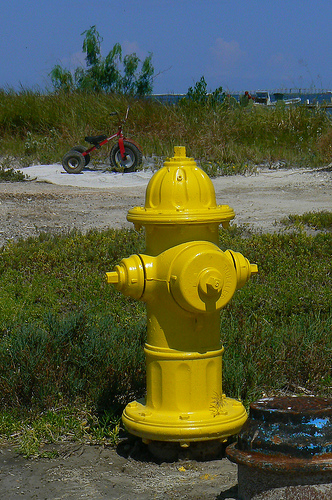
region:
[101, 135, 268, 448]
yellow hydrant in front of weeds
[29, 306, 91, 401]
green weeds on ground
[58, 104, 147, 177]
red tricycle parked on sand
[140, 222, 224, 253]
shadow under hydrant cover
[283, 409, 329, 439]
blue paint on rusty cover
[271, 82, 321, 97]
bridge over water on horizon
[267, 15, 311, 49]
blue of daytime sky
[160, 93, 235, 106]
body of water behind weeds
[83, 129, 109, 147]
black seat on bicycle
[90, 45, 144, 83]
green leaves on tree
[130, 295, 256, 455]
a yellow water pipe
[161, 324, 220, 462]
a yellow water pipe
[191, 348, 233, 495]
a yellow water pipe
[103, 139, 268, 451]
a bright yellow fire hydrant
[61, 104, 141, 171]
a black and red tricycle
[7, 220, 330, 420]
a patch of green grass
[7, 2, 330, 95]
a cloudy blue sky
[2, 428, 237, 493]
grey paved concrete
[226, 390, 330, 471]
a rusty blue top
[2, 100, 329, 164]
a patch of tall grass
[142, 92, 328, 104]
a blue body of water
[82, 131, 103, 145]
a tricycle black seat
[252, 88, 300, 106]
a white boat in distance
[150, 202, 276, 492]
a yellow water pipe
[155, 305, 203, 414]
a yellow water pipe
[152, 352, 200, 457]
a yellow water pipe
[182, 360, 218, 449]
a yellow water pipe